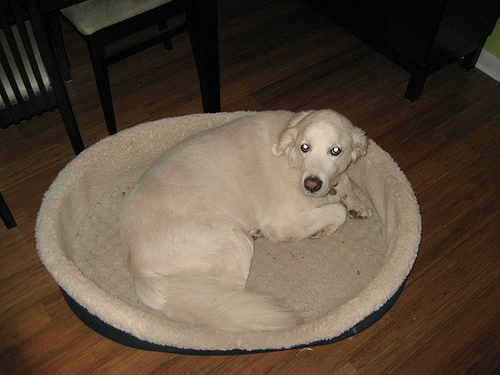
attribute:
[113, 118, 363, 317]
dog — white, medium, looking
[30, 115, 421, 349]
bed — black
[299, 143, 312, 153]
eye — bright, shining, open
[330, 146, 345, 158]
eye — bright, shining, open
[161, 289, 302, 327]
tail — fluffy, white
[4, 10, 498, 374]
floor — wooden, brown, laminate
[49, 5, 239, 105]
chair — wooden, black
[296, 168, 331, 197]
snout — brown, pink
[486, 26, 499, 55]
wall — green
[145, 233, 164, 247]
hair — white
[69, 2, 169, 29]
cushion — white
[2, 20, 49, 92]
cushion — white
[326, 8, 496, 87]
cabinet — wooden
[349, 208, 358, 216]
pad — dark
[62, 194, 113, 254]
inside — beige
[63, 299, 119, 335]
outside — black